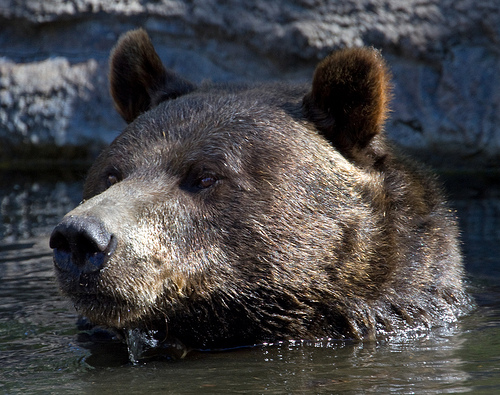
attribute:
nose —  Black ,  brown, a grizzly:
[55, 211, 145, 263]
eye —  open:
[189, 166, 221, 194]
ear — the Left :
[299, 44, 396, 160]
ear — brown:
[108, 22, 387, 147]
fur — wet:
[83, 270, 473, 343]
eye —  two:
[192, 172, 220, 191]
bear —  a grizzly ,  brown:
[45, 52, 334, 379]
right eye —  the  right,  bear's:
[87, 164, 138, 205]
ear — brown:
[298, 49, 390, 151]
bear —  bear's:
[32, 34, 499, 389]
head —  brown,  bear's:
[38, 17, 493, 364]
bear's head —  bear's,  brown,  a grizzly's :
[50, 25, 475, 362]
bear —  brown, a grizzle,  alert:
[42, 26, 480, 361]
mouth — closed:
[83, 285, 182, 337]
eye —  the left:
[97, 170, 125, 188]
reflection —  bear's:
[298, 336, 470, 392]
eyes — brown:
[96, 163, 237, 199]